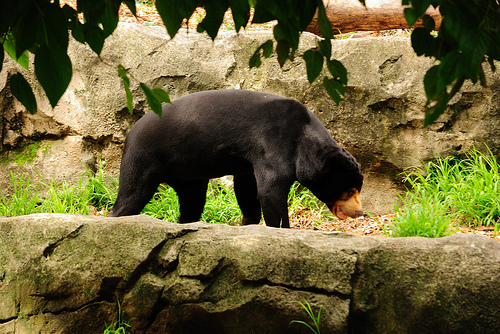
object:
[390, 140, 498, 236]
grass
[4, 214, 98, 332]
wall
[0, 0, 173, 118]
tree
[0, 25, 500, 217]
wall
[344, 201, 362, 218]
nose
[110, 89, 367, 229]
bear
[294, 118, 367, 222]
head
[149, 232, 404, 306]
rock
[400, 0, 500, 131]
leaves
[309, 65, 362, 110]
leaf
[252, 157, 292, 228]
leg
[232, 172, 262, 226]
leg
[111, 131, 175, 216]
leg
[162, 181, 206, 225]
leg